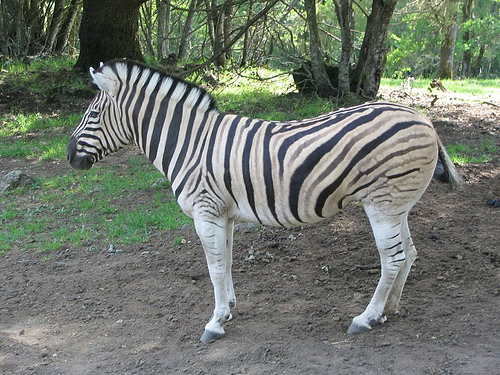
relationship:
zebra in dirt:
[68, 54, 468, 345] [0, 89, 498, 370]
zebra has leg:
[68, 54, 468, 345] [194, 216, 231, 345]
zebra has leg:
[68, 54, 468, 345] [226, 223, 237, 308]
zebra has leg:
[68, 54, 468, 345] [348, 208, 403, 332]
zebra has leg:
[68, 54, 468, 345] [388, 218, 415, 313]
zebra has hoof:
[68, 54, 468, 345] [200, 327, 225, 346]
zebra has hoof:
[68, 54, 468, 345] [345, 318, 369, 336]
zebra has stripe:
[68, 54, 468, 345] [259, 122, 281, 227]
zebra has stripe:
[68, 54, 468, 345] [242, 120, 260, 225]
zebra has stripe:
[68, 54, 468, 345] [223, 113, 241, 210]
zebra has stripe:
[68, 54, 468, 345] [164, 91, 203, 188]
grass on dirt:
[6, 55, 497, 253] [0, 89, 498, 370]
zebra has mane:
[68, 54, 468, 345] [87, 59, 214, 114]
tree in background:
[307, 3, 397, 96] [0, 5, 495, 97]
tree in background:
[79, 1, 150, 75] [0, 5, 495, 97]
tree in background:
[188, 2, 293, 68] [0, 5, 495, 97]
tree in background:
[421, 0, 484, 82] [0, 5, 495, 97]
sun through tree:
[224, 63, 300, 91] [307, 3, 397, 96]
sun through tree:
[224, 63, 300, 91] [188, 2, 293, 68]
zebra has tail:
[68, 54, 468, 345] [436, 137, 462, 194]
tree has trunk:
[79, 1, 150, 75] [73, 3, 146, 70]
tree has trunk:
[188, 2, 293, 68] [209, 1, 277, 62]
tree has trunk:
[307, 3, 397, 96] [304, 1, 330, 95]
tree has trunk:
[307, 3, 397, 96] [333, 3, 358, 87]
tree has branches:
[188, 2, 293, 68] [240, 11, 292, 51]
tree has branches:
[188, 2, 293, 68] [150, 3, 208, 45]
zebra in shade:
[68, 54, 468, 345] [0, 97, 479, 375]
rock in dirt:
[1, 165, 48, 191] [0, 89, 498, 370]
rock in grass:
[1, 165, 48, 191] [6, 55, 497, 253]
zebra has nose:
[68, 54, 468, 345] [64, 137, 87, 170]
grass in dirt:
[6, 55, 497, 253] [0, 89, 498, 370]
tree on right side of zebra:
[421, 0, 484, 82] [68, 54, 468, 345]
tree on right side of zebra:
[307, 3, 397, 96] [68, 54, 468, 345]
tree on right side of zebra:
[188, 2, 293, 68] [68, 54, 468, 345]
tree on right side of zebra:
[79, 1, 150, 75] [68, 54, 468, 345]